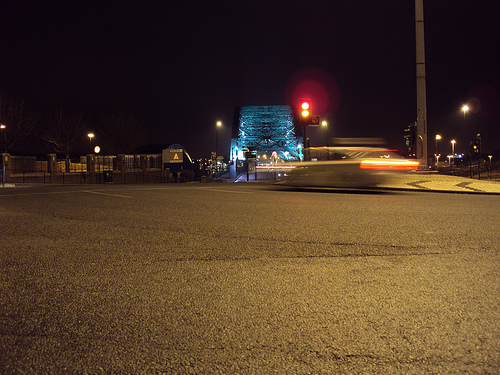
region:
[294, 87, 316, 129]
a traffic light in the street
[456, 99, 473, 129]
a street light is on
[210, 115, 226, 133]
a street light is on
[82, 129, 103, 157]
the street lights are on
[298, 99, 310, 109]
a red light of traffic light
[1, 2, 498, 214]
the scene is the night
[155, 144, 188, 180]
a sign on side a road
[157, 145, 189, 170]
sign has a triangle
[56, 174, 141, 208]
white lines on the road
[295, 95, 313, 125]
a stop light at an intersection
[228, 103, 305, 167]
a bridge lit up at night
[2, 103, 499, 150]
Street lamps lighting up an area at night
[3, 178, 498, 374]
road pavement at an intersection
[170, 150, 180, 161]
warning sign on the back of a trailer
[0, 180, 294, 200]
road markings at an intersection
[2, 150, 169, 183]
a fence along a road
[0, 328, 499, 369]
a crack in in the road pavement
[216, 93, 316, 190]
a blue bridge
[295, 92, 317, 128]
a red light lit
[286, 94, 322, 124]
a yellow light under red light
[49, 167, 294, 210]
lines on the ground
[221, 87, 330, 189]
a lit up blue bridge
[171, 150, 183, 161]
a red and white caution sign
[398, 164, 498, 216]
two black arrows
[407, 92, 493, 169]
several lit street lights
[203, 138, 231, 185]
tall buildings in the distance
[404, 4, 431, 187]
a tall pole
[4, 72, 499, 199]
lights are on a bridge with steel trusses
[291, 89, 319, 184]
a traffic signal is next to the bridge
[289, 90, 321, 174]
the traffic signal is on a black pole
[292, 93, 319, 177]
both the red and orange lights are on the signal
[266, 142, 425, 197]
a car is zooming through the signal light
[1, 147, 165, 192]
a stone wall is by the side of the bridge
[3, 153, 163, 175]
a fence is on top of the wall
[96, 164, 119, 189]
a trash receptacle is next to the wall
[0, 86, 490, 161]
street lamps are around the bridge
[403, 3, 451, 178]
a tall pole is near the bridge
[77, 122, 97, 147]
a bright light outside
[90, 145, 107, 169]
a bright light outside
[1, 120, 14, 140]
a bright light outside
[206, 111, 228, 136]
a bright light outside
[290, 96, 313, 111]
a bright light outside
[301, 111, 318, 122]
a bright light outside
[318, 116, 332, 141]
a bright light outside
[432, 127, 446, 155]
a bright light outside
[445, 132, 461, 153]
a bright light outside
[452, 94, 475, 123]
a bright light outside